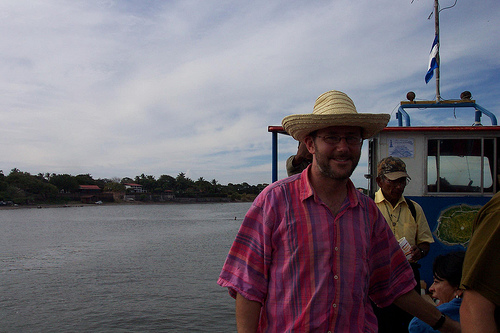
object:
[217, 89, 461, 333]
man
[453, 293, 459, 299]
earring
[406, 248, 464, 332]
woman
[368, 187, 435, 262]
shirt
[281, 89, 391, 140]
officerhat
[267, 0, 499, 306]
boat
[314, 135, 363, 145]
glasses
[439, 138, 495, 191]
window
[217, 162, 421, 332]
shirt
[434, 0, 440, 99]
pole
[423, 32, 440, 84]
flag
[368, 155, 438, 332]
man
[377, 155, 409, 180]
cap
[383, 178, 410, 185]
glasses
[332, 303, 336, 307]
buttons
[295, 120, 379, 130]
underside